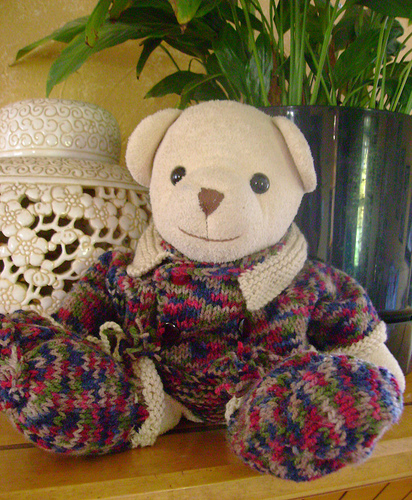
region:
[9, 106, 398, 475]
a white teddy bear on a shelf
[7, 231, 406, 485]
a multi-color knit outfit for the bear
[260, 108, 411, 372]
a black plastic planter behind the bear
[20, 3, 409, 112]
a large green plant in the planter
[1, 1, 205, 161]
yellow walks behind the plant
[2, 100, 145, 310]
a decorative white vase behind the bear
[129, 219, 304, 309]
the bear's white collar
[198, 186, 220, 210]
the bear's brown nose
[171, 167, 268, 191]
the bear's black eyes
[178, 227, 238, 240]
the bear's thin mouth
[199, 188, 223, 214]
a brown triangle nose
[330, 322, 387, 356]
white cuff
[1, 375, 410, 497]
the table top is wood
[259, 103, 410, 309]
the pot is reflective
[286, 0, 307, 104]
green stems on the plants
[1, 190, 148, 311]
flower design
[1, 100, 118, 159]
a circular pattern on the pot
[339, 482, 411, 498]
lines on the table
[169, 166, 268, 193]
the bear has black eyes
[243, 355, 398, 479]
a knitted shoe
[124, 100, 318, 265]
Round teddy bear face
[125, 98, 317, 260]
Beige teddy bear head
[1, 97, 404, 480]
Teddy bear beside a vase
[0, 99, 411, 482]
Plush bear wearing a sweater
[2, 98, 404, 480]
Stuffed bear dressed in a sweater and socks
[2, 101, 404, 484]
Teddy bear wearing multi-colored clothes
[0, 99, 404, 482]
Porcelain vase next to a stuffed animal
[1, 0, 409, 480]
Stuffed bear in front of a potted plant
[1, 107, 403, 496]
Stuffed animal sitting on a tabletop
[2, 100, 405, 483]
Teddy bear with socks on his feet